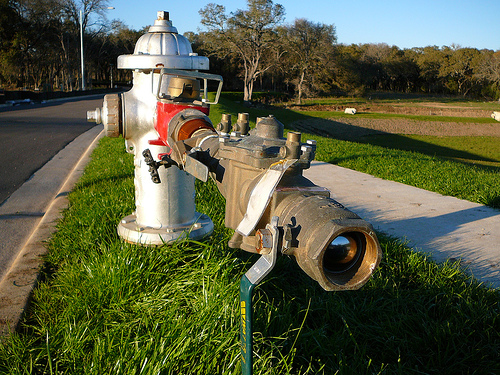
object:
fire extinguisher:
[165, 107, 379, 375]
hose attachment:
[149, 102, 216, 161]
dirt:
[301, 117, 499, 140]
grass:
[0, 95, 500, 375]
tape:
[161, 99, 191, 113]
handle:
[235, 274, 258, 375]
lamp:
[78, 0, 85, 90]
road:
[0, 90, 131, 278]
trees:
[268, 16, 338, 107]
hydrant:
[87, 10, 224, 248]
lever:
[237, 214, 285, 374]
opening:
[317, 229, 381, 290]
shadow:
[212, 97, 500, 165]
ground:
[291, 95, 500, 175]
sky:
[0, 0, 500, 52]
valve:
[142, 148, 170, 184]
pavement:
[300, 160, 499, 301]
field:
[0, 97, 500, 375]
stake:
[245, 255, 276, 286]